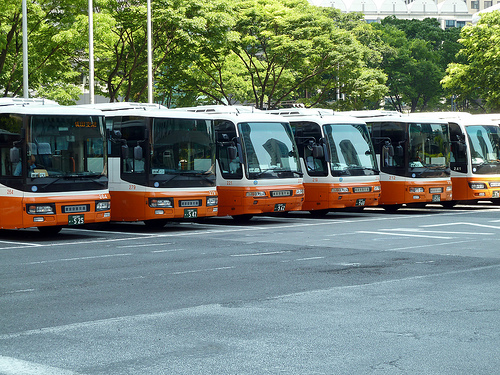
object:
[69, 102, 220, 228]
bus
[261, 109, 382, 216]
bus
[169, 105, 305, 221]
bus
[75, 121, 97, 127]
sign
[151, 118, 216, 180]
windshield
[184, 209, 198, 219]
license plate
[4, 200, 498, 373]
lot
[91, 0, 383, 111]
tree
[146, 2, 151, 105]
pole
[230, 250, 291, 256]
mark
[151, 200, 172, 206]
light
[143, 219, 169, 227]
tire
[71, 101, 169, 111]
unit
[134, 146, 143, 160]
mirror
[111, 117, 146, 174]
window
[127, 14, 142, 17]
leaf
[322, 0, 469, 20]
wall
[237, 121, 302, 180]
windshield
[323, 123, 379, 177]
windshield